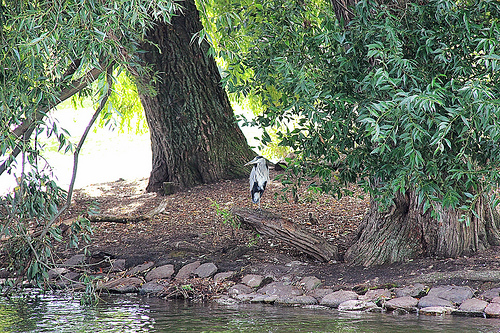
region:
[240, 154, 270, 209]
bird standing on log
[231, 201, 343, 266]
brown wooden tree limb on ground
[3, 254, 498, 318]
large rocks double layered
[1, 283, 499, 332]
rock edged water pond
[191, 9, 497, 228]
large green leaves on tree on right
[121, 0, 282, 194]
large mossy tree trunk on left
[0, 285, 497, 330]
water is rippled and reflective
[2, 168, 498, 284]
brown leaves on ground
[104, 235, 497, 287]
dark brown mud under tree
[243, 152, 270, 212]
bird is white and black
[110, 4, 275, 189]
A large tree trunk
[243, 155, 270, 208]
A large black and white bird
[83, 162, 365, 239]
A leaf covered hill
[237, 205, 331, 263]
A log on the ground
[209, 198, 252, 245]
A plant in the leaves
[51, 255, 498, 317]
A rocky shore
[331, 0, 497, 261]
A large tree trunk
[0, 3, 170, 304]
A large overhanging branch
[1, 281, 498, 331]
A body of water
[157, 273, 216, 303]
A pile of twigs and leaves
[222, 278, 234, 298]
part of a rock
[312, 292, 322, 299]
edge of a rock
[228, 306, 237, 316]
part of a river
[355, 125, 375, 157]
part of a bush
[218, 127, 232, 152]
edge of a stem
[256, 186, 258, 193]
part of a bird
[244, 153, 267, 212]
gray, white, and black colored bird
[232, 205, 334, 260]
a log laying on the ground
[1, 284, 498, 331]
green colored calm water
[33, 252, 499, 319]
rocks on the bank of the water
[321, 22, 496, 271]
a large tree stump with vegetation growing from it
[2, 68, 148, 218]
sun reflecting on the ground and on the water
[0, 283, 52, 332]
tree reflecting in the water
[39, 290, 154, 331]
sunlight reflecting on the water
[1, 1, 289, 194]
large tree with green leaves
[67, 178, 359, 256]
leaves and dead branches on the ground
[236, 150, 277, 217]
bird by the water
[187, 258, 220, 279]
rock near the water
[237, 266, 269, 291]
rock near the water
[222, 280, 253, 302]
rock near the water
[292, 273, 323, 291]
rock near the water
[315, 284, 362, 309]
rock near the water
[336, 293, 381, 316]
rock near the water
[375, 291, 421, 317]
rock near the water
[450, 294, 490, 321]
rock near the water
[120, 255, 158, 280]
rock near the water